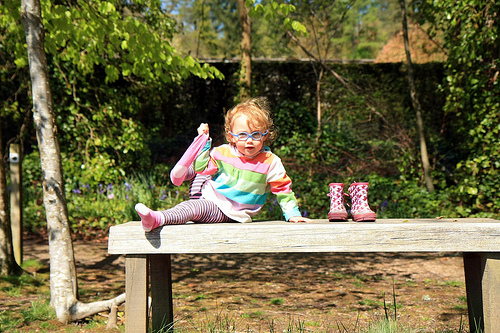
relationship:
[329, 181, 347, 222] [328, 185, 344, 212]
boot has spots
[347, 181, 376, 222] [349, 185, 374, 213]
boot has spots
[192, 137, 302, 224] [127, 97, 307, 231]
stripes on child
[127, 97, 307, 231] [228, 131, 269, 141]
child has glasses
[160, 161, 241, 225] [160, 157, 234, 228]
stripes have stripes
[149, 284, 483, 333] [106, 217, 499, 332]
grass under bench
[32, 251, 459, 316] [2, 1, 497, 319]
shadows from trees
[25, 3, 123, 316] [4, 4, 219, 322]
trunk of tree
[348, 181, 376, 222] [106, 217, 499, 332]
boot are on bench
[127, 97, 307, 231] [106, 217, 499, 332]
child on bench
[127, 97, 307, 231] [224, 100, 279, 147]
child has blonde hair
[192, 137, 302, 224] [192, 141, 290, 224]
stripes has stripes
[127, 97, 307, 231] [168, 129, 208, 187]
girl pulling sock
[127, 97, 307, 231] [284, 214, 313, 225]
girl leaning on hand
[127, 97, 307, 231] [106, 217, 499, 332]
girl on bench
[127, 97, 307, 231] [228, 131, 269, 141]
girl wearing glasses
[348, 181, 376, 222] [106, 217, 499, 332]
boot are on table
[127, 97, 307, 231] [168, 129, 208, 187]
girl pulling on sock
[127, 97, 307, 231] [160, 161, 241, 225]
girl has striped stripes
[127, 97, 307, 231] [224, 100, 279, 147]
girl has red hair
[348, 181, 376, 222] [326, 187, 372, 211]
boot have pink hearts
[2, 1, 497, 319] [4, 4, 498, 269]
trees in background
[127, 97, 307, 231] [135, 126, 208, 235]
girl has pink socks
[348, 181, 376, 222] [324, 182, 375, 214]
boot have spots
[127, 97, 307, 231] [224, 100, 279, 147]
child has red hair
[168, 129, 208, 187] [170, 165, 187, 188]
sock being pulled on right foot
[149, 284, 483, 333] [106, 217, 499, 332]
weeds under bench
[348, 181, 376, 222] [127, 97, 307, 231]
boot belong to child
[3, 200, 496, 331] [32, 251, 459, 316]
ground has shadows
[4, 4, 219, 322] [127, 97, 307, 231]
tree left of child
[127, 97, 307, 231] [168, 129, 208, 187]
girl removing sock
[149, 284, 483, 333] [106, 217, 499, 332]
grass growing in front of bench